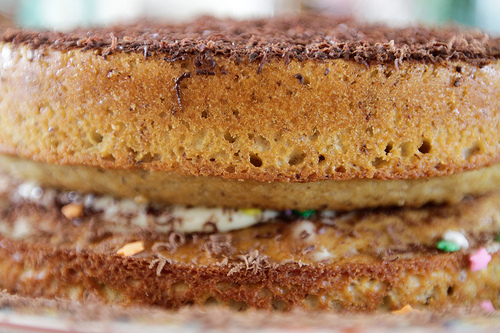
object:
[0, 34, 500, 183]
crust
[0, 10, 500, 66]
top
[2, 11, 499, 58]
crust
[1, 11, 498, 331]
dessert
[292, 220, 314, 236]
sprinkle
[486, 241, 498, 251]
sprinkle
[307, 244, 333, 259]
sprinkle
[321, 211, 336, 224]
sprinkle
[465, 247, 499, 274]
sprinkle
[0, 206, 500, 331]
cake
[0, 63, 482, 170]
layer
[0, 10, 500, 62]
chocolate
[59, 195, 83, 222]
sprinkle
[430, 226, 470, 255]
sprinkle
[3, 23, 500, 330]
creram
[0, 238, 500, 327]
crust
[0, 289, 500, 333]
plate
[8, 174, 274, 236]
icing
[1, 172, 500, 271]
shaving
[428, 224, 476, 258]
confetti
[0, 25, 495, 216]
bread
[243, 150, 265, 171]
holes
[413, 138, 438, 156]
holes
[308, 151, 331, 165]
holes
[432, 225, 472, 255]
cream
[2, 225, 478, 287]
chocolate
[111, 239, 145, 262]
orange confetti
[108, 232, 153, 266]
sprinkle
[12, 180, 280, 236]
cream filling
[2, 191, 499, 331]
layer